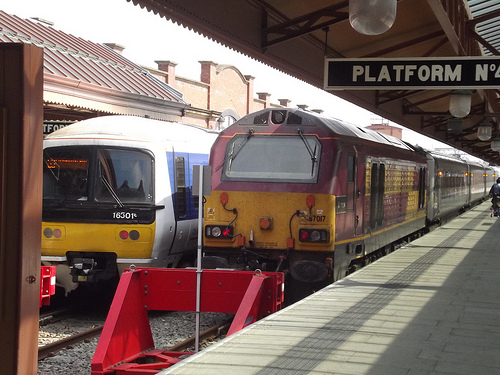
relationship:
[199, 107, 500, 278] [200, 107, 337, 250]
train have end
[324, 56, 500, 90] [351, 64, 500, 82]
sign tells platform number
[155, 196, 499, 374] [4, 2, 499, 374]
walkway in train station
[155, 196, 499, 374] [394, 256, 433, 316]
walkway have a part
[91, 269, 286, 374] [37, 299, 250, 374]
blockade on track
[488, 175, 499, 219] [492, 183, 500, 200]
person has back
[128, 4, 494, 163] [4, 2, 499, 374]
roof in train station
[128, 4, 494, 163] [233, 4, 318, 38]
roof have a part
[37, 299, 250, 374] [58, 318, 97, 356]
track have a part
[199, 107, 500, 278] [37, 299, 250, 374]
train in track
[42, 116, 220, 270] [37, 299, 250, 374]
train in track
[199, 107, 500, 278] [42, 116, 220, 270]
train next to train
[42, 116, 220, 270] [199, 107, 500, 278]
train next to train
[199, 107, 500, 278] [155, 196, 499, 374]
train next to walkway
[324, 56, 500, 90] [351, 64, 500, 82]
sign have platform number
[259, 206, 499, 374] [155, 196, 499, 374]
shadow on walkway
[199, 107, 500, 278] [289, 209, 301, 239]
train have a cord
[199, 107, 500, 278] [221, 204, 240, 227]
train have a cord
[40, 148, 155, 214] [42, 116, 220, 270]
windshield on train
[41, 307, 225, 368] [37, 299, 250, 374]
gravel between track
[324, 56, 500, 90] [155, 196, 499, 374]
sign on walkway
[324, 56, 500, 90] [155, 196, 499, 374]
sign above walkway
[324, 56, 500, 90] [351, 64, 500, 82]
sign for platform number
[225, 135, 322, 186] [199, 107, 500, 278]
window on train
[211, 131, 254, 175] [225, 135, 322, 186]
windshield wiper on window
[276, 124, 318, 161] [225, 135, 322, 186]
windshield wiper on window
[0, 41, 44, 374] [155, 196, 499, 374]
bearn at side of walkway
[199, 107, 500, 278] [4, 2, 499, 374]
train in train station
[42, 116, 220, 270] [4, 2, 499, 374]
train in train station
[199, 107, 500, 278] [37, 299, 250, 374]
train on track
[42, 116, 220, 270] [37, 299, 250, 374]
train on track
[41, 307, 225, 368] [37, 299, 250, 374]
gravel underneath track